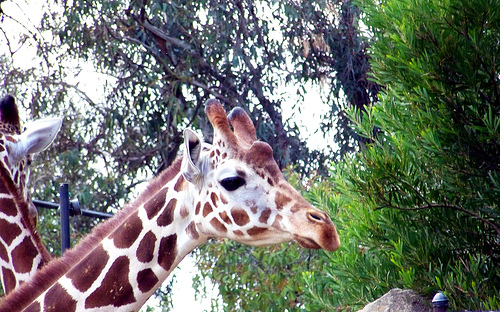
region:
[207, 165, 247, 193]
the giraffes eye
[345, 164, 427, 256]
the leaves on the tree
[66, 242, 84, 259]
the hair is brown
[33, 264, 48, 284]
the giraffes hair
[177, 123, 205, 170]
the ear on the giraffe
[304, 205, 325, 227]
the nose of the giraffe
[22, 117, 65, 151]
the ear of the giraffe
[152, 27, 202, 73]
tree branches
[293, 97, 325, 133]
the sky is clear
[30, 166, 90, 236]
a black pole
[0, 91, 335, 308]
two giraffes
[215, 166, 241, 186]
the eye of the giraffe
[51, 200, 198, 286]
the neck of the giraffe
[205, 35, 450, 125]
trees behind the giraffe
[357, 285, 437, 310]
a rock under the tree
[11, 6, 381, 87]
the sky through the trees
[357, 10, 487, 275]
leaves on the tree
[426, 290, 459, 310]
the top of a pole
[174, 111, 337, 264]
the face of a giraffe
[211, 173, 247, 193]
left eye of the giraffe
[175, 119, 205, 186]
right ear on giraffe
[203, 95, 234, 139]
horn on right side of giraffe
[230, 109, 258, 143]
horn on left side of giraffe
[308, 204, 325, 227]
nose on the giraffe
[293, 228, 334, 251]
the mouth of the giraffe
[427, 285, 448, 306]
hat on the person's head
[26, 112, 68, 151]
ear on the giraffe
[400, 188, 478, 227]
sticks on the trees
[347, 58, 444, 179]
leaves on the tree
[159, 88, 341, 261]
head of a giraffe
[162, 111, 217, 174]
ear of a giraffe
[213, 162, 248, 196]
eye of a giraffe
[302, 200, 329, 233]
nose of a giraffe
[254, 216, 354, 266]
mouth of a giraffe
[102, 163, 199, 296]
neck of a giraffe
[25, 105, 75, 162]
ear of a giraffe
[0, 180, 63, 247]
neck of a giraffe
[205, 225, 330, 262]
jaw of a giraffe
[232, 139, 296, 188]
forehead of a giraffe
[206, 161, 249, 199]
giraffe's eye is black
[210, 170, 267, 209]
giraffe's eye is black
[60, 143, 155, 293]
giraffe's fur is brown and white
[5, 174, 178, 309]
giraffe's fur is brown and white